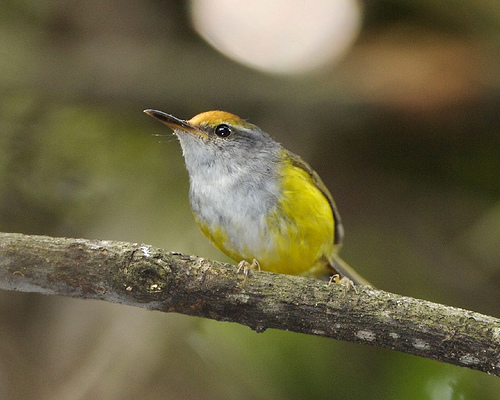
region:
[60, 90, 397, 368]
this is a yellow bird on the tree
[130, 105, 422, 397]
this is acolourful bird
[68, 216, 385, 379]
this is a tree branch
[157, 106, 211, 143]
the bird has a sharp beak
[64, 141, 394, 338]
this is an outdoor image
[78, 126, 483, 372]
what a lovely bird very beautiful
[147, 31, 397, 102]
this is a good shot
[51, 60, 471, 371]
i love this image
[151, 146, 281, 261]
it also has a white patch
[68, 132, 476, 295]
this bird is very beautiful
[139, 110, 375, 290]
Yellow, white and gray bird.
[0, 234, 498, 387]
Little gray branch from tree.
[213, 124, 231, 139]
Small black round bird eye.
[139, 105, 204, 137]
Black and tan bird beak.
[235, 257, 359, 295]
Bird claws on tree branch.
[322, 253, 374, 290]
Bird's gray tail feathers.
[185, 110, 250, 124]
Bird's orange top of head.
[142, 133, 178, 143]
Bird's tiny little whiskers.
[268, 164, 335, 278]
Bird's yellow under belly.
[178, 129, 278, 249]
Bird's white under body.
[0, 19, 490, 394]
This picture is taken outside.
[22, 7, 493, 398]
Picture is taken during the day.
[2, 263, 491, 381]
A tree branch appears in the picture.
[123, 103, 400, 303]
A bird is sitting on the branch.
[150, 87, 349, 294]
The bird has yellow feathers.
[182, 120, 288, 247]
Some of the bird's feathers are white.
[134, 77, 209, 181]
The bird's beak is small and long.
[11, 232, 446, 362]
The branch has light green, grey and tan colors on it.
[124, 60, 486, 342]
The bird is looking to the left.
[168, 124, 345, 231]
You can only see the left side of the bird's face.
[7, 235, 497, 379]
tree branch with spots of white on it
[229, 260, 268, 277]
foot of bird holding onto bench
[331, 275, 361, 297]
foot of bird holding onto bench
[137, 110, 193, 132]
birds beak with yellow on bottom and black on top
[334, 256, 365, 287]
birds tail with black and yellow feathers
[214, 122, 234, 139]
small bright eye of a bird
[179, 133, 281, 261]
birds chest and throat with white feathers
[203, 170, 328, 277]
body of bird with yellow feathers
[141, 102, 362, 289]
bird sitting on tree branch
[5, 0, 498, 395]
blurred background behind sitting bird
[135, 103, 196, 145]
a long black and yellow beak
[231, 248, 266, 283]
small, delicate bird foot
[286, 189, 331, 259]
bright yellow feathers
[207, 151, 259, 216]
white and grey feathers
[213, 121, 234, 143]
a small bright eye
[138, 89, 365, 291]
a small white and yellow bird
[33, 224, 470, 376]
a long, thin tree branch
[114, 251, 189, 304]
a small knot in the wood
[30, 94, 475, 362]
a small bird perched on a branch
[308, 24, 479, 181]
a blurry background